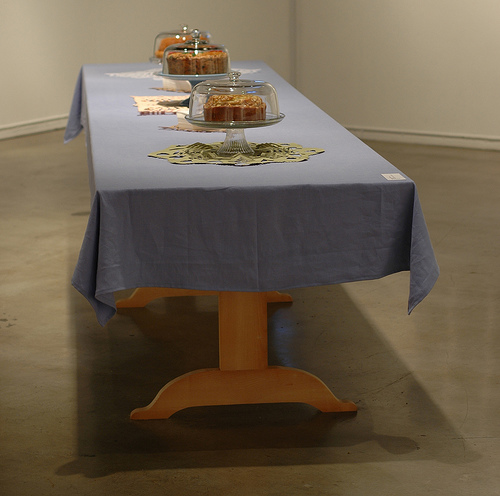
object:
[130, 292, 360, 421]
leg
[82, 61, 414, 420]
table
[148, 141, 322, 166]
doily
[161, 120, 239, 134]
mat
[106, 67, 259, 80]
doily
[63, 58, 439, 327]
tablecloth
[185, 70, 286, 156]
cake dish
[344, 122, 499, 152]
baseboard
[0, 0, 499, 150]
wall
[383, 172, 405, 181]
card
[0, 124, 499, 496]
floor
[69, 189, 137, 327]
corner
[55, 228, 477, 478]
shadow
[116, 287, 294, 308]
leg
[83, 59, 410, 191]
top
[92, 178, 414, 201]
edge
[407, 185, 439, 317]
corner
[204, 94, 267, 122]
cake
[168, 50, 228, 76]
cake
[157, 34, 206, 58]
cake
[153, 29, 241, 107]
cake dish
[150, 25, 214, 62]
cake dish